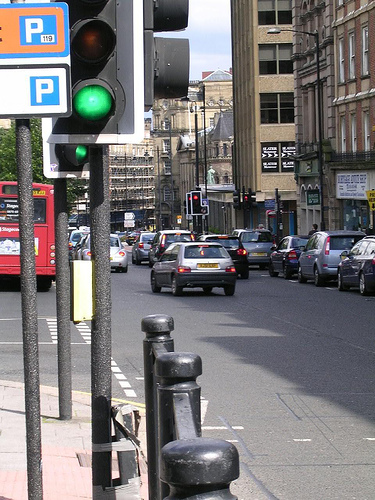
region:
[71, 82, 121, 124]
Green traffic light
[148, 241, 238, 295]
Light colored car going down the street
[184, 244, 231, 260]
Back windshield of light colored car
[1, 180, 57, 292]
Red bus on left side of street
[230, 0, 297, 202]
Tall sandy colored building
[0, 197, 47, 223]
Back windshield of red bus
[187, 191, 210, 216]
Red stop light in the distance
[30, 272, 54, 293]
Right rear tire of the red bu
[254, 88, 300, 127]
Window in light colored building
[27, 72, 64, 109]
Blue and white street sign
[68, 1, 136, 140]
Green traffic light.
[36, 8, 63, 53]
Blue and Orange parking sign on post.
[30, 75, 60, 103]
Blue and white parking sign on post.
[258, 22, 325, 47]
City street light.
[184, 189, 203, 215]
Two red traffic lights.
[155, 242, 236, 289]
Grey car with yellow tag.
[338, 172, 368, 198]
Sign on front of business.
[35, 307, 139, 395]
Markings in the street.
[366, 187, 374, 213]
Yellow road sign.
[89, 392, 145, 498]
Poles held together with duct tape.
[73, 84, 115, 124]
green traffic light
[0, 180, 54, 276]
red bus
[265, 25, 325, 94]
overhead street lamp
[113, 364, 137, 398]
white painted lines on a city street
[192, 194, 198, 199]
red traffic light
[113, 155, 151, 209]
scaffolding in front of a building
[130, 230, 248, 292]
cars driving on a city street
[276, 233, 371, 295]
cars parked along a city street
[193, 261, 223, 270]
yellow license plate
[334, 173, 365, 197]
blue and white sign above a store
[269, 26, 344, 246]
A street light.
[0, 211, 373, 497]
The road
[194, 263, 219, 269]
A yellow and black license plate.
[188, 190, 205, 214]
A traffic light displaying a red light.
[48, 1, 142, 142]
A black and white traffic light with a green light.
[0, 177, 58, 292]
The back of a red bus.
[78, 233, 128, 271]
A silver VW beetle.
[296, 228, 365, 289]
A silver minivan.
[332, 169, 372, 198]
A white sign with blue lettering on a building.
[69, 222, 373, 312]
Vehicles driving down the road.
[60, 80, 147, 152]
the light is green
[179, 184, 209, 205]
the light is red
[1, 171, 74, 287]
the bus is red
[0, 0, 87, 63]
sign is orange and blue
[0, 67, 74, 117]
sign is white and black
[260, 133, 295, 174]
signs are black and white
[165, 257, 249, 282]
car's light is red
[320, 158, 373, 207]
the sign is white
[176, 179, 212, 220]
street light is black and white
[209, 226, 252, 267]
the car is black